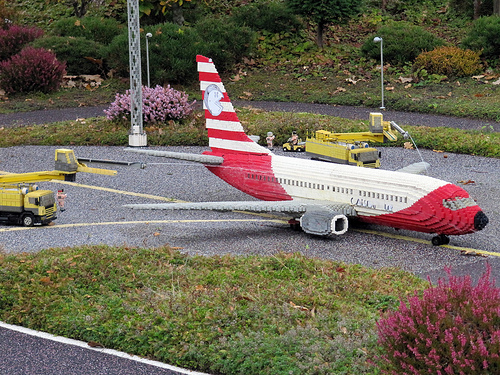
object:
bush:
[376, 259, 500, 374]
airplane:
[117, 53, 488, 249]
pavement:
[2, 145, 498, 291]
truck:
[303, 111, 406, 170]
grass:
[1, 108, 500, 157]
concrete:
[2, 99, 499, 293]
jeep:
[281, 136, 306, 153]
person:
[288, 130, 300, 145]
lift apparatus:
[315, 111, 407, 142]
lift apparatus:
[0, 148, 116, 190]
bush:
[105, 82, 196, 130]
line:
[1, 323, 212, 374]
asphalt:
[0, 323, 199, 374]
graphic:
[202, 83, 226, 118]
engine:
[296, 207, 349, 238]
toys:
[1, 143, 119, 232]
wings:
[394, 161, 430, 175]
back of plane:
[123, 50, 291, 202]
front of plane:
[386, 177, 488, 233]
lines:
[53, 181, 500, 257]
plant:
[317, 68, 326, 79]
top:
[116, 83, 185, 99]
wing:
[119, 199, 357, 215]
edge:
[122, 205, 348, 213]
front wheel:
[431, 235, 443, 247]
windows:
[331, 185, 336, 192]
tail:
[194, 53, 277, 156]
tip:
[475, 210, 488, 231]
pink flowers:
[190, 100, 197, 107]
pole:
[124, 0, 148, 146]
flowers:
[441, 328, 455, 344]